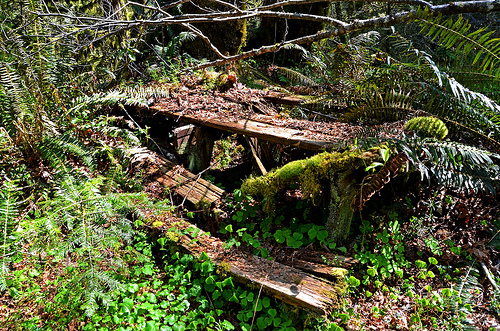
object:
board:
[143, 81, 378, 153]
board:
[127, 194, 347, 318]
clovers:
[68, 188, 406, 331]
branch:
[11, 0, 499, 73]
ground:
[0, 158, 498, 330]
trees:
[0, 2, 500, 78]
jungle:
[1, 2, 499, 330]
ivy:
[440, 264, 484, 322]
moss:
[238, 149, 364, 215]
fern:
[0, 31, 162, 180]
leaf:
[409, 7, 500, 78]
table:
[136, 140, 360, 277]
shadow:
[213, 214, 317, 285]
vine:
[202, 250, 290, 331]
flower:
[227, 71, 237, 84]